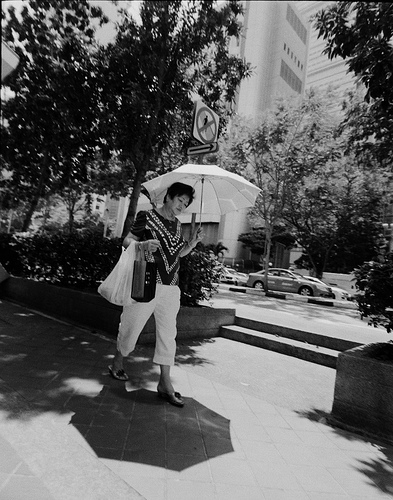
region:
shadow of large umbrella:
[80, 384, 251, 462]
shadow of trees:
[327, 440, 385, 494]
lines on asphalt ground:
[238, 383, 295, 433]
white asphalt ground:
[260, 442, 349, 484]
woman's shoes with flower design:
[160, 385, 199, 410]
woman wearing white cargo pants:
[97, 280, 209, 367]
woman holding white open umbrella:
[139, 154, 269, 219]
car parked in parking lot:
[249, 263, 334, 307]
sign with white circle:
[181, 90, 248, 155]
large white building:
[242, 4, 326, 114]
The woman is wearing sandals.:
[92, 347, 205, 406]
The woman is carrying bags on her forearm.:
[92, 229, 162, 306]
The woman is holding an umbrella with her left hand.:
[142, 145, 252, 258]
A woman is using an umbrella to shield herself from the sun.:
[85, 147, 253, 414]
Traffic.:
[210, 250, 366, 310]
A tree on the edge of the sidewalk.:
[220, 100, 339, 297]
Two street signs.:
[174, 99, 236, 170]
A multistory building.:
[193, 0, 361, 154]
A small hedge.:
[10, 222, 206, 301]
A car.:
[247, 263, 333, 299]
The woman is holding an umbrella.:
[130, 143, 273, 245]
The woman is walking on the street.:
[94, 151, 269, 408]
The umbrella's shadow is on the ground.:
[60, 368, 264, 483]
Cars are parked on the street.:
[193, 257, 356, 298]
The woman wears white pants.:
[100, 274, 193, 372]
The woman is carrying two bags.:
[83, 222, 161, 315]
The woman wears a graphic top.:
[122, 204, 200, 297]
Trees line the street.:
[1, 3, 256, 312]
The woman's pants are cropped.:
[103, 279, 198, 371]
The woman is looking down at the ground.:
[146, 175, 203, 226]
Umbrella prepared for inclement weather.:
[142, 160, 248, 273]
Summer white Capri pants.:
[137, 180, 185, 383]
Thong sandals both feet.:
[102, 346, 188, 406]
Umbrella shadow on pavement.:
[58, 399, 246, 483]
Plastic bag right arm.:
[94, 228, 134, 312]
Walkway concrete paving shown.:
[239, 392, 319, 483]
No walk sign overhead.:
[188, 95, 231, 141]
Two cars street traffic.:
[248, 263, 357, 302]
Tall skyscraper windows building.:
[261, 1, 322, 136]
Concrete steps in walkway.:
[217, 306, 374, 378]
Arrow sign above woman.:
[187, 143, 216, 155]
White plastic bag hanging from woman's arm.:
[98, 235, 134, 309]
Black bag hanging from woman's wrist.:
[129, 238, 157, 311]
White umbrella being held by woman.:
[137, 155, 262, 215]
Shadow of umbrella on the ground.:
[65, 380, 246, 472]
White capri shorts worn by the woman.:
[122, 278, 179, 368]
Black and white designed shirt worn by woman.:
[140, 208, 191, 288]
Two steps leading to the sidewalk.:
[224, 306, 357, 372]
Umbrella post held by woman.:
[198, 179, 204, 235]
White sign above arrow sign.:
[199, 96, 222, 142]